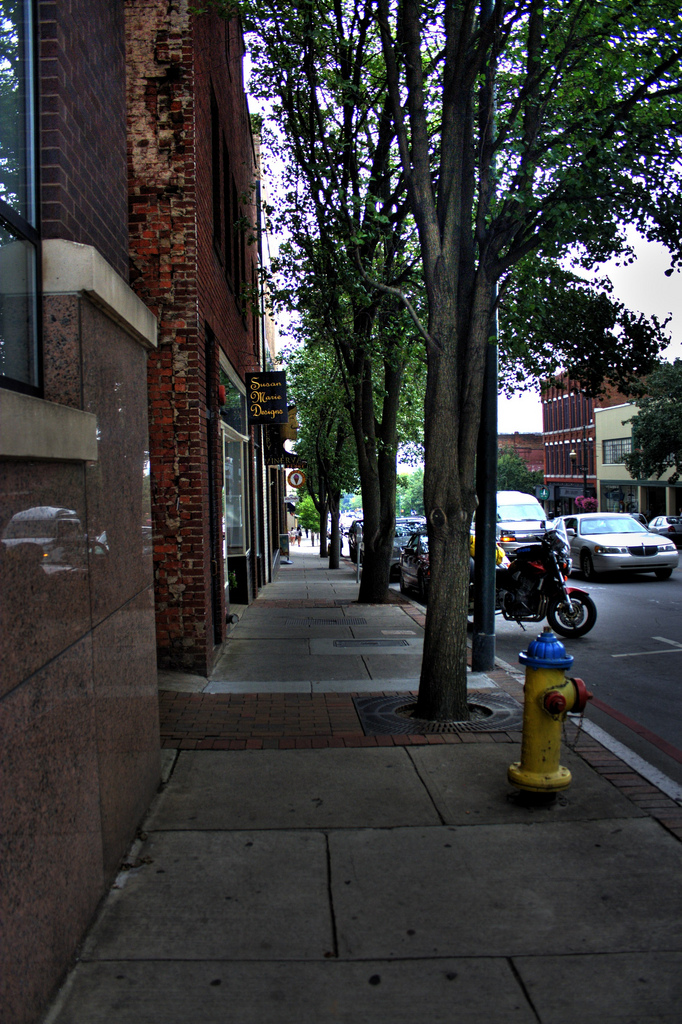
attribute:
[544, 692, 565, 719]
lug — red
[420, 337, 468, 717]
tree trunk — brown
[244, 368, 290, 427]
sign — black, yellow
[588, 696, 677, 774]
line — red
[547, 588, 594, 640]
wheel — front wheel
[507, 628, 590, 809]
fire hydrant — yellow, blue, red, green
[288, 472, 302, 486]
sign — red, white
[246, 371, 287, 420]
sign — gold, black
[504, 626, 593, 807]
hydrant — blue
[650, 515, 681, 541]
car — parked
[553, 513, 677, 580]
car — white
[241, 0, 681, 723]
tree — green, leafy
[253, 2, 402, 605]
tree — green, leafy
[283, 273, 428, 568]
tree — green, leafy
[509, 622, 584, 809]
fire hydrant — yellow, blue, red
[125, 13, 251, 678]
building — brick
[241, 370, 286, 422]
sign — black, yellow, shop sign